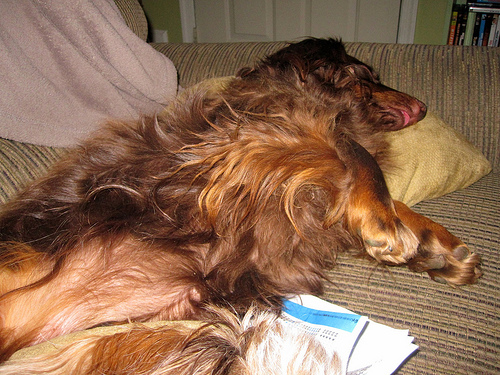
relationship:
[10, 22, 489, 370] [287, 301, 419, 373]
dog on paper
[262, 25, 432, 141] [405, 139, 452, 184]
head on pillow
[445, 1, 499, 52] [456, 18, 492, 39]
bookshelf has books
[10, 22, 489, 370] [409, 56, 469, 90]
dog laying on couch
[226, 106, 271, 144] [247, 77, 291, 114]
patch of hair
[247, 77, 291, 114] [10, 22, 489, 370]
hair on dog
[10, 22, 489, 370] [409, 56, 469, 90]
dog on couch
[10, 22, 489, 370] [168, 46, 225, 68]
dog on sofa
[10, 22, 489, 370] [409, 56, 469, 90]
dog sleeping on couch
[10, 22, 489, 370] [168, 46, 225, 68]
dog sleeping on sofa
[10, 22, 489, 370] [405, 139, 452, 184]
dog laying on a pillow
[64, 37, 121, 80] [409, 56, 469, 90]
blanket on couch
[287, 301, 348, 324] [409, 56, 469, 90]
paper on couch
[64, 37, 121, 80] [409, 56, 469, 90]
blanket on back of couch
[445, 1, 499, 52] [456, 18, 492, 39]
shelf has books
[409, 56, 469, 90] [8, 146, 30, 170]
couch has stripes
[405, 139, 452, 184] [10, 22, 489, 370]
pillow under dog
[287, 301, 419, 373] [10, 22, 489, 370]
paper are laying by dog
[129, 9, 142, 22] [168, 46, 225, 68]
fabric on sofa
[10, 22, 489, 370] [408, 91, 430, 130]
dog has a snout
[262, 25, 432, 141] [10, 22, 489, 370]
head of dog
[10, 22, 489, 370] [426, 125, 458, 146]
dog resting on a cushion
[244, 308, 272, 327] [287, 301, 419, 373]
sheaf of paper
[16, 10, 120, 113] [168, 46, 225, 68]
towel thrown on sofa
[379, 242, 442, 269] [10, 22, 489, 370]
paws of dog